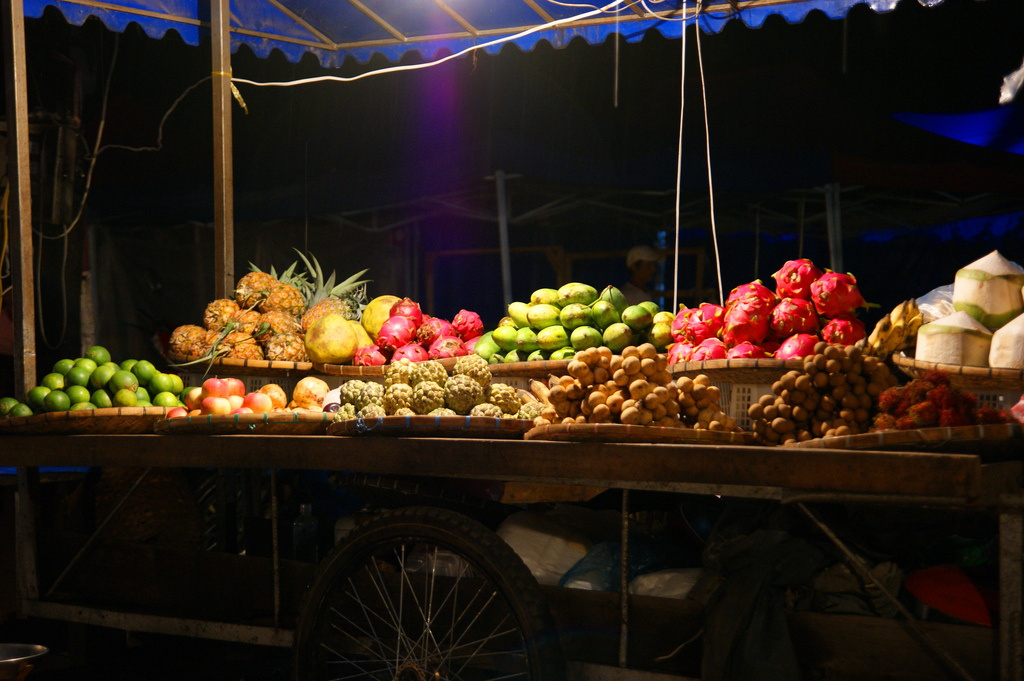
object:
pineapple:
[329, 354, 545, 423]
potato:
[534, 343, 744, 434]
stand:
[2, 248, 1023, 452]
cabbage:
[354, 296, 485, 365]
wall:
[49, 69, 969, 242]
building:
[16, 0, 1023, 478]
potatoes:
[748, 342, 901, 446]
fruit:
[0, 249, 1024, 445]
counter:
[0, 248, 1024, 502]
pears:
[0, 346, 197, 418]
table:
[0, 388, 1024, 681]